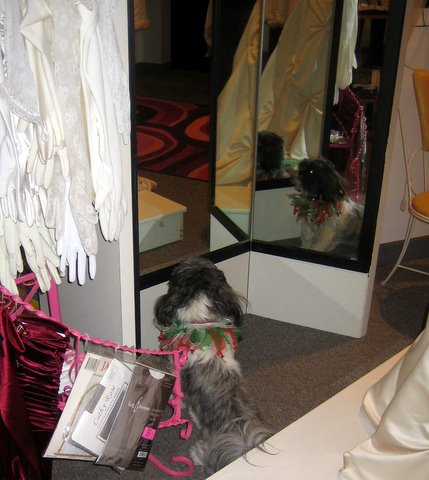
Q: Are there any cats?
A: No, there are no cats.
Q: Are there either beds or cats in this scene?
A: No, there are no cats or beds.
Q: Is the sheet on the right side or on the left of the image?
A: The sheet is on the right of the image.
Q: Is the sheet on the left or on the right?
A: The sheet is on the right of the image.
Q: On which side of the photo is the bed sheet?
A: The bed sheet is on the right of the image.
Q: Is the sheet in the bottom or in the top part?
A: The sheet is in the bottom of the image.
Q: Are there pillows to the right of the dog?
A: No, there is a sheet to the right of the dog.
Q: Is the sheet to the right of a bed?
A: No, the sheet is to the right of the dog.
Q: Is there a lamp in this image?
A: No, there are no lamps.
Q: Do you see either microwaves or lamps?
A: No, there are no lamps or microwaves.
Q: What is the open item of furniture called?
A: The piece of furniture is a wardrobe.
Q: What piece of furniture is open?
A: The piece of furniture is a wardrobe.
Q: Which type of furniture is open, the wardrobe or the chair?
A: The wardrobe is open.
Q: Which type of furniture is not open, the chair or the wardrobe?
A: The chair is not open.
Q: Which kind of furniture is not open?
A: The furniture is a chair.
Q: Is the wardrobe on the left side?
A: Yes, the wardrobe is on the left of the image.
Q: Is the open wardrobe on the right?
A: No, the wardrobe is on the left of the image.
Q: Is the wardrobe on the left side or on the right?
A: The wardrobe is on the left of the image.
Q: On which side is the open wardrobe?
A: The wardrobe is on the left of the image.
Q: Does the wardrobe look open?
A: Yes, the wardrobe is open.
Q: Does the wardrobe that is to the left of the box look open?
A: Yes, the wardrobe is open.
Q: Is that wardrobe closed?
A: No, the wardrobe is open.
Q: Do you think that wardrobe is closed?
A: No, the wardrobe is open.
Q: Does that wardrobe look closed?
A: No, the wardrobe is open.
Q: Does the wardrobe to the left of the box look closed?
A: No, the wardrobe is open.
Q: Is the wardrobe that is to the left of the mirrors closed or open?
A: The wardrobe is open.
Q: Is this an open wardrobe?
A: Yes, this is an open wardrobe.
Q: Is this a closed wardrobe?
A: No, this is an open wardrobe.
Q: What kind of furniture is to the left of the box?
A: The piece of furniture is a wardrobe.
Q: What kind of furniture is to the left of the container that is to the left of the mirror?
A: The piece of furniture is a wardrobe.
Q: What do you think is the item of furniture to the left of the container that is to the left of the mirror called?
A: The piece of furniture is a wardrobe.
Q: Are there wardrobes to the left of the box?
A: Yes, there is a wardrobe to the left of the box.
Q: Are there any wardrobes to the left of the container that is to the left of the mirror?
A: Yes, there is a wardrobe to the left of the box.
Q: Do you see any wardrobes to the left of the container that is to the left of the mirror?
A: Yes, there is a wardrobe to the left of the box.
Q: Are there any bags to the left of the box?
A: No, there is a wardrobe to the left of the box.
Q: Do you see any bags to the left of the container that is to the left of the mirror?
A: No, there is a wardrobe to the left of the box.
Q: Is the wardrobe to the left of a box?
A: Yes, the wardrobe is to the left of a box.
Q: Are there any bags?
A: No, there are no bags.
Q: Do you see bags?
A: No, there are no bags.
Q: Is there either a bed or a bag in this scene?
A: No, there are no bags or beds.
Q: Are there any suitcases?
A: No, there are no suitcases.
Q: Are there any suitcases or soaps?
A: No, there are no suitcases or soaps.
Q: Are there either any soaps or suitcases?
A: No, there are no suitcases or soaps.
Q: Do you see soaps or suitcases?
A: No, there are no suitcases or soaps.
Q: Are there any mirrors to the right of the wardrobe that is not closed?
A: Yes, there are mirrors to the right of the wardrobe.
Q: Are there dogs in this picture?
A: Yes, there is a dog.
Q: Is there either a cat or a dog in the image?
A: Yes, there is a dog.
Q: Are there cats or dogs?
A: Yes, there is a dog.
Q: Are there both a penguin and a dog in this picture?
A: No, there is a dog but no penguins.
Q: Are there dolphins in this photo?
A: No, there are no dolphins.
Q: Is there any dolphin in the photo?
A: No, there are no dolphins.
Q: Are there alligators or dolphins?
A: No, there are no dolphins or alligators.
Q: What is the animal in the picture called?
A: The animal is a dog.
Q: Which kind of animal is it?
A: The animal is a dog.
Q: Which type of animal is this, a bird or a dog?
A: This is a dog.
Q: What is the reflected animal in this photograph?
A: The animal is a dog.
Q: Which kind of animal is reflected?
A: The animal is a dog.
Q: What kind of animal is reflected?
A: The animal is a dog.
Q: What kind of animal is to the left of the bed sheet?
A: The animal is a dog.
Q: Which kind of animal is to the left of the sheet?
A: The animal is a dog.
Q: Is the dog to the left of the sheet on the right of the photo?
A: Yes, the dog is to the left of the bed sheet.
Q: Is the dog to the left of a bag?
A: No, the dog is to the left of the bed sheet.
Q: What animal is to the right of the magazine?
A: The animal is a dog.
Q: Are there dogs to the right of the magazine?
A: Yes, there is a dog to the right of the magazine.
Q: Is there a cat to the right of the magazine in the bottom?
A: No, there is a dog to the right of the magazine.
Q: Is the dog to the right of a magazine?
A: Yes, the dog is to the right of a magazine.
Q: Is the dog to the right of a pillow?
A: No, the dog is to the right of a magazine.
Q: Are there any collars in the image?
A: Yes, there is a collar.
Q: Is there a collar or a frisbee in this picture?
A: Yes, there is a collar.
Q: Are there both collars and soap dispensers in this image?
A: No, there is a collar but no soap dispensers.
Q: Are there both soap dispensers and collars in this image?
A: No, there is a collar but no soap dispensers.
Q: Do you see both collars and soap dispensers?
A: No, there is a collar but no soap dispensers.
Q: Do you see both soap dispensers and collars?
A: No, there is a collar but no soap dispensers.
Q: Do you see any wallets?
A: No, there are no wallets.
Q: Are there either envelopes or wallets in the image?
A: No, there are no wallets or envelopes.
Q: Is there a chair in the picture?
A: Yes, there is a chair.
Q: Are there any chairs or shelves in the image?
A: Yes, there is a chair.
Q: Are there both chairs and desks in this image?
A: No, there is a chair but no desks.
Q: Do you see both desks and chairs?
A: No, there is a chair but no desks.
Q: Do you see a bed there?
A: No, there are no beds.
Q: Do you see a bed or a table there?
A: No, there are no beds or tables.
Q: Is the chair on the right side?
A: Yes, the chair is on the right of the image.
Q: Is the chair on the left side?
A: No, the chair is on the right of the image.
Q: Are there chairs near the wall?
A: Yes, there is a chair near the wall.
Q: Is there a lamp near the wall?
A: No, there is a chair near the wall.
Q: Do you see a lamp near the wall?
A: No, there is a chair near the wall.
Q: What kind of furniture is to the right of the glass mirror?
A: The piece of furniture is a chair.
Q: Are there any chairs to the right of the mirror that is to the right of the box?
A: Yes, there is a chair to the right of the mirror.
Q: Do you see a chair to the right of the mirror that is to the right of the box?
A: Yes, there is a chair to the right of the mirror.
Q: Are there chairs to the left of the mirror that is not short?
A: No, the chair is to the right of the mirror.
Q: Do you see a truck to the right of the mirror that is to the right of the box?
A: No, there is a chair to the right of the mirror.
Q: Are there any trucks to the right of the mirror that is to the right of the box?
A: No, there is a chair to the right of the mirror.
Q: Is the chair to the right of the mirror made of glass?
A: Yes, the chair is to the right of the mirror.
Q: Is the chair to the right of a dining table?
A: No, the chair is to the right of the mirror.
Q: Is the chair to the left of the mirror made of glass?
A: No, the chair is to the right of the mirror.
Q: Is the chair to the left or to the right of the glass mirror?
A: The chair is to the right of the mirror.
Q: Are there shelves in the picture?
A: No, there are no shelves.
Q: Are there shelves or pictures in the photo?
A: No, there are no shelves or pictures.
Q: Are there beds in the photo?
A: No, there are no beds.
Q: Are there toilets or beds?
A: No, there are no beds or toilets.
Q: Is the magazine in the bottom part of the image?
A: Yes, the magazine is in the bottom of the image.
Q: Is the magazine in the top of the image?
A: No, the magazine is in the bottom of the image.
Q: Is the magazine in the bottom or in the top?
A: The magazine is in the bottom of the image.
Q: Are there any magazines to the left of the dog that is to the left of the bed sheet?
A: Yes, there is a magazine to the left of the dog.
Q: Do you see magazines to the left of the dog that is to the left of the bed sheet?
A: Yes, there is a magazine to the left of the dog.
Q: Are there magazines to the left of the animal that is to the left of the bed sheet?
A: Yes, there is a magazine to the left of the dog.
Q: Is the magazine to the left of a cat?
A: No, the magazine is to the left of the dog.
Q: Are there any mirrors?
A: Yes, there is a mirror.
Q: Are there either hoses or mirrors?
A: Yes, there is a mirror.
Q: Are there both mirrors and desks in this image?
A: No, there is a mirror but no desks.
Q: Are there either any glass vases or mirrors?
A: Yes, there is a glass mirror.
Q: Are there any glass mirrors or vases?
A: Yes, there is a glass mirror.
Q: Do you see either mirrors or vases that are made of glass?
A: Yes, the mirror is made of glass.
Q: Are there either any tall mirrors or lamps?
A: Yes, there is a tall mirror.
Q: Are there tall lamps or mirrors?
A: Yes, there is a tall mirror.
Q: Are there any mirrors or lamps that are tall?
A: Yes, the mirror is tall.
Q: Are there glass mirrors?
A: Yes, there is a mirror that is made of glass.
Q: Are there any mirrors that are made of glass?
A: Yes, there is a mirror that is made of glass.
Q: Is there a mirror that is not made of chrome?
A: Yes, there is a mirror that is made of glass.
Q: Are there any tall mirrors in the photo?
A: Yes, there is a tall mirror.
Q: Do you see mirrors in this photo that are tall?
A: Yes, there is a mirror that is tall.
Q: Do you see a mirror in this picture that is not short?
A: Yes, there is a tall mirror.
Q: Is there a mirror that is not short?
A: Yes, there is a tall mirror.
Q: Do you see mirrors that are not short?
A: Yes, there is a tall mirror.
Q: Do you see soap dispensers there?
A: No, there are no soap dispensers.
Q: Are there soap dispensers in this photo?
A: No, there are no soap dispensers.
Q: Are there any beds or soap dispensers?
A: No, there are no soap dispensers or beds.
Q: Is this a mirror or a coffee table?
A: This is a mirror.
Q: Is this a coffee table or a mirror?
A: This is a mirror.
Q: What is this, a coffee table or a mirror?
A: This is a mirror.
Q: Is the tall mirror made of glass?
A: Yes, the mirror is made of glass.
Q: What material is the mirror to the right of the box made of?
A: The mirror is made of glass.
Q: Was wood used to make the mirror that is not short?
A: No, the mirror is made of glass.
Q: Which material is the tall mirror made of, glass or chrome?
A: The mirror is made of glass.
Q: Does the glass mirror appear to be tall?
A: Yes, the mirror is tall.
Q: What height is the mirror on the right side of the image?
A: The mirror is tall.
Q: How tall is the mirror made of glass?
A: The mirror is tall.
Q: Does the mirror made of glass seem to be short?
A: No, the mirror is tall.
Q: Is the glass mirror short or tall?
A: The mirror is tall.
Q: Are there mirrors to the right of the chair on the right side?
A: No, the mirror is to the left of the chair.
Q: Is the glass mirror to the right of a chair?
A: No, the mirror is to the left of a chair.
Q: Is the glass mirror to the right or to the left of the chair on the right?
A: The mirror is to the left of the chair.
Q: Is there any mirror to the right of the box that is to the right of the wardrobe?
A: Yes, there is a mirror to the right of the box.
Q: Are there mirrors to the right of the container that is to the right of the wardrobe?
A: Yes, there is a mirror to the right of the box.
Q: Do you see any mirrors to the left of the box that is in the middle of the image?
A: No, the mirror is to the right of the box.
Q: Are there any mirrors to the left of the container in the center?
A: No, the mirror is to the right of the box.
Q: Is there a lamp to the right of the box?
A: No, there is a mirror to the right of the box.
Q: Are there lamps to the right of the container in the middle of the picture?
A: No, there is a mirror to the right of the box.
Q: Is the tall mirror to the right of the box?
A: Yes, the mirror is to the right of the box.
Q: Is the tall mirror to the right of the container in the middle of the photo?
A: Yes, the mirror is to the right of the box.